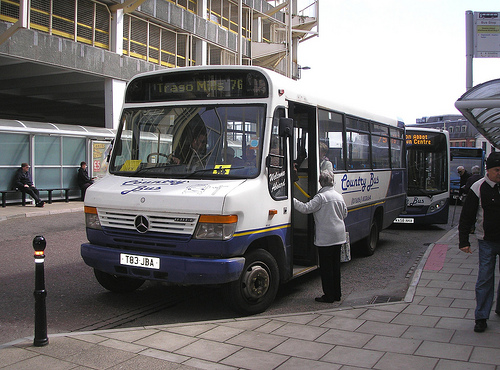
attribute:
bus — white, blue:
[113, 71, 412, 288]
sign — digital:
[406, 132, 433, 144]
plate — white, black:
[115, 249, 160, 271]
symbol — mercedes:
[16, 201, 189, 329]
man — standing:
[454, 149, 499, 336]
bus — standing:
[58, 38, 498, 308]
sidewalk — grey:
[1, 231, 499, 368]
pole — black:
[33, 232, 51, 346]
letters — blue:
[339, 172, 381, 194]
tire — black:
[218, 244, 277, 314]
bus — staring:
[82, 65, 408, 312]